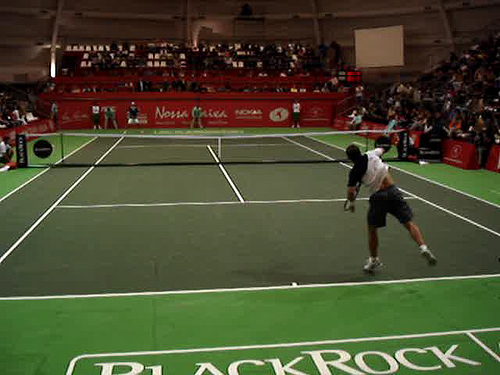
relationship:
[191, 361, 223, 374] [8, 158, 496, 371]
letter on ground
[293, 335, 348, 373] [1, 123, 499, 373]
letter on ground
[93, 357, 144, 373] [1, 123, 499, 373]
letter on ground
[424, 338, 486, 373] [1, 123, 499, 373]
letter on ground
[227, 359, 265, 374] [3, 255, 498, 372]
white letter on ground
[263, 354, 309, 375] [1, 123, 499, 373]
letter on ground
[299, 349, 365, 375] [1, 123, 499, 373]
letter on ground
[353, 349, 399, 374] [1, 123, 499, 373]
letter on ground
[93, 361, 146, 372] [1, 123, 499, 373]
letter on ground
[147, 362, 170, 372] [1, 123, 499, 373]
letter on ground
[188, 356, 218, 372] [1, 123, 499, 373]
letter on ground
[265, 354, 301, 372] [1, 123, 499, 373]
letter on ground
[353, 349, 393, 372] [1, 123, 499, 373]
letter on ground